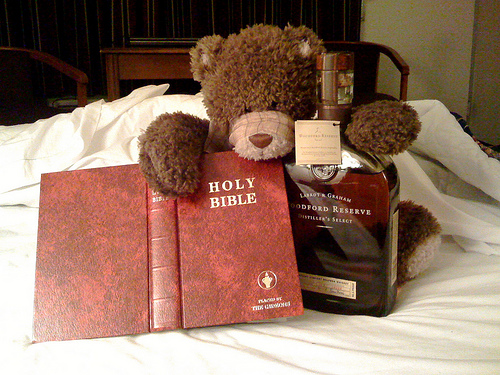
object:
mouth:
[254, 147, 269, 156]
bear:
[137, 22, 442, 287]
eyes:
[244, 106, 251, 115]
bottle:
[282, 51, 400, 316]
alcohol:
[282, 51, 400, 318]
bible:
[33, 149, 305, 342]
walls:
[352, 0, 493, 120]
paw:
[132, 122, 214, 194]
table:
[101, 44, 200, 101]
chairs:
[318, 42, 414, 108]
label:
[294, 119, 342, 165]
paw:
[354, 100, 421, 155]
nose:
[248, 133, 273, 148]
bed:
[1, 80, 493, 372]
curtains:
[323, 8, 359, 86]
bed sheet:
[0, 85, 494, 370]